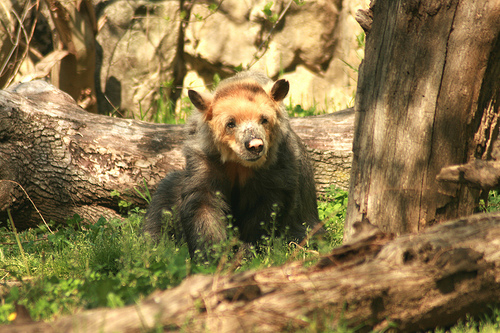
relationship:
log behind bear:
[3, 85, 363, 226] [138, 68, 327, 269]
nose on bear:
[238, 129, 265, 156] [135, 77, 332, 275]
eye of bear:
[226, 118, 237, 128] [135, 77, 332, 275]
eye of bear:
[260, 117, 268, 125] [135, 77, 332, 275]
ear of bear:
[269, 78, 291, 100] [138, 68, 327, 269]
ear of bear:
[184, 87, 210, 112] [135, 77, 332, 275]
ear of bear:
[269, 78, 291, 100] [135, 77, 332, 275]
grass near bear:
[4, 190, 347, 315] [135, 77, 332, 275]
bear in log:
[146, 50, 317, 222] [3, 85, 363, 226]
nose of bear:
[211, 109, 270, 190] [158, 64, 408, 290]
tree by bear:
[319, 45, 442, 288] [161, 70, 351, 284]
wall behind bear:
[289, 50, 356, 219] [177, 38, 349, 263]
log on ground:
[104, 251, 438, 316] [53, 91, 450, 321]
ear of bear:
[269, 78, 291, 100] [159, 62, 373, 292]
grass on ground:
[4, 190, 347, 315] [21, 130, 483, 322]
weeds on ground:
[97, 190, 221, 278] [21, 130, 483, 322]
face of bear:
[193, 70, 328, 206] [168, 70, 363, 320]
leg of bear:
[173, 163, 349, 290] [149, 50, 351, 267]